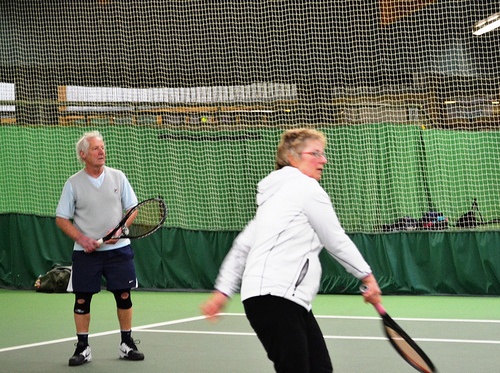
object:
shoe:
[69, 342, 92, 366]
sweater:
[67, 165, 132, 252]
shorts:
[66, 244, 139, 293]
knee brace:
[73, 292, 92, 315]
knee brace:
[109, 287, 132, 309]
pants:
[241, 294, 333, 372]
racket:
[359, 284, 437, 373]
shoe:
[119, 338, 145, 360]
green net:
[0, 0, 500, 232]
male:
[55, 130, 144, 365]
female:
[199, 128, 382, 373]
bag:
[33, 263, 71, 293]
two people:
[54, 128, 381, 372]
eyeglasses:
[298, 150, 328, 158]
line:
[0, 315, 207, 352]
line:
[133, 329, 499, 344]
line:
[215, 312, 499, 323]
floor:
[0, 289, 499, 372]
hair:
[275, 128, 327, 171]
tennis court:
[0, 288, 499, 373]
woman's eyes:
[314, 151, 321, 158]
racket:
[77, 198, 168, 258]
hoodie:
[212, 166, 373, 313]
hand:
[76, 234, 100, 253]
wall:
[0, 0, 500, 296]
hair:
[76, 131, 106, 167]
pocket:
[294, 258, 309, 290]